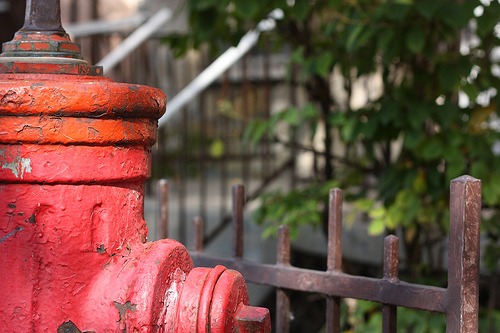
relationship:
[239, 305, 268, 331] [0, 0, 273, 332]
bolt on fire hydrant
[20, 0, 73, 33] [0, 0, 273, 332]
bolt on fire hydrant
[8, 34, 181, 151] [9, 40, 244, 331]
top on fire hydrant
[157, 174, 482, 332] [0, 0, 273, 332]
fence near fire hydrant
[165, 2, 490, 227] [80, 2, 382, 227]
green tree by building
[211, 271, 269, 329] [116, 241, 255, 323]
cap on outlet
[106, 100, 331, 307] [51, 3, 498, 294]
steps into building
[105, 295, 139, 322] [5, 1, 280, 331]
paint on fire hydrant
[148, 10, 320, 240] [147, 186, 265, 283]
railing for stairs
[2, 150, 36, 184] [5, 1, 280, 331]
scratch on fire hydrant